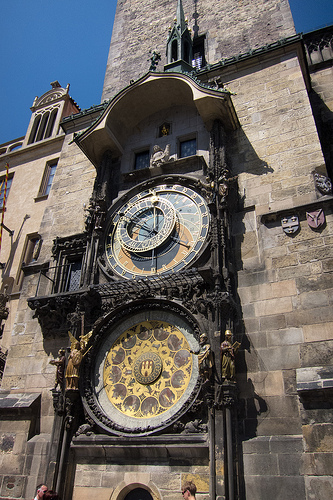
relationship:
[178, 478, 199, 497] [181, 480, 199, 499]
head of a person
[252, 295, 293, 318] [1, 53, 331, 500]
brick inside a wall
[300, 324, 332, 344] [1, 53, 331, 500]
brick inside a wall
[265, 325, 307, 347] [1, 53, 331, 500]
brick inside a wall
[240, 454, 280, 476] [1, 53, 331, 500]
brick inside a wall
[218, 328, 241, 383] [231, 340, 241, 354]
man holding something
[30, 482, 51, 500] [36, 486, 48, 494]
man wearing glasses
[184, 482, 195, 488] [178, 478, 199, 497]
top of head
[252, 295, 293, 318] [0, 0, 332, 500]
brick on side of a building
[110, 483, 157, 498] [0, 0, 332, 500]
opening of building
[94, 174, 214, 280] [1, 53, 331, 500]
clock hanging on a wall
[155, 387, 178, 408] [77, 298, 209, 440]
symbol inside a circle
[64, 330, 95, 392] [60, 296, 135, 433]
statue standing on left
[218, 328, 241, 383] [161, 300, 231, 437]
man standing on right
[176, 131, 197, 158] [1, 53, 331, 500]
window hanging on wall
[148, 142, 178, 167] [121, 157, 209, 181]
statue sitting on top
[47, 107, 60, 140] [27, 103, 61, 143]
window lined in a row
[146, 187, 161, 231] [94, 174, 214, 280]
hand on front of clock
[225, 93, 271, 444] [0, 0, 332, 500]
shadow on front of building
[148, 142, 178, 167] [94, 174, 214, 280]
statue sitting above clock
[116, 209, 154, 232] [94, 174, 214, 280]
hand on front of clock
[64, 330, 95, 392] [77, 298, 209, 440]
statue standing next to circle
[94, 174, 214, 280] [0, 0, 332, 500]
clock on front of a building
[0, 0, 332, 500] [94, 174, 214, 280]
building with a clock